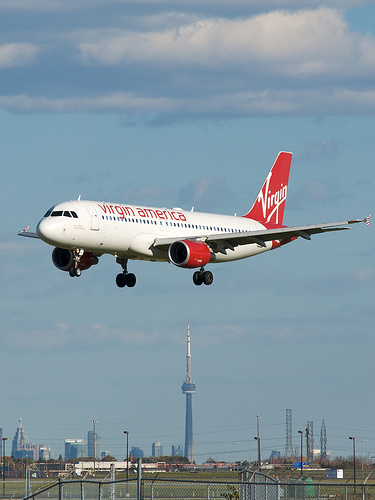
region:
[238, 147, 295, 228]
the tail of a plane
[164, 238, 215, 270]
the engine of a plane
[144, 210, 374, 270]
the wing of a plane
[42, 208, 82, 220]
the windshield of a plane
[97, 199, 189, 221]
red writing on the plane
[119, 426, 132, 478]
a black light pole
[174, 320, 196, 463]
a tower in the distance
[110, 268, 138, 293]
a wheel of the plane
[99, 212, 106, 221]
a window on the plane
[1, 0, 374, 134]
clouds in the sky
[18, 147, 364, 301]
this is a plane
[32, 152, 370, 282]
the plane is white in color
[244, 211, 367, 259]
this is the wing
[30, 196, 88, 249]
the head is streamlined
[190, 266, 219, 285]
these are the wheels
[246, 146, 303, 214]
this is the tail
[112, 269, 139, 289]
the wheels are black in color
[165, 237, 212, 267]
this is the propeller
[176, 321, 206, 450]
the tower is tall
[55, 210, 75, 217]
the screen are black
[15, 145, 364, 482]
plane close to landing near industrial town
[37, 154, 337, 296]
white plane with red writing and red highlights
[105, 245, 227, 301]
black wheels underneath the plane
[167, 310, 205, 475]
tall spire towering over other buildings and structures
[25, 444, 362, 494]
metal fencing near plane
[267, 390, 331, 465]
tall metal structures connected to wires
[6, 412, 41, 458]
old and heavy tiered building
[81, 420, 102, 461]
modern building with slanted roof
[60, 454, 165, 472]
wide and short white building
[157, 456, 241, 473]
series of red signs in front of spire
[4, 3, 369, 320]
The sky is blue.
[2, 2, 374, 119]
The clouds are white.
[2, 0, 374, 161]
The sky is partly cloudy.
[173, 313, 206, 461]
One tall building.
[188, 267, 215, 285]
The wheels are black.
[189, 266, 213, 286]
The wheels are round.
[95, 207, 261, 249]
Windows on the plane.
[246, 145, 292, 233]
Tale is red and white.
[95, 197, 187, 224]
Text says Virgin America.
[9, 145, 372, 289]
Airplane in the sky.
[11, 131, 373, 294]
airplane in the sky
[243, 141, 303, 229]
tail of an airplane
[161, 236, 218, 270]
left engine of a plane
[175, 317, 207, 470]
sky tower at an airport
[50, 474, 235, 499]
silver chain link fence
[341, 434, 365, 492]
light poles by the runway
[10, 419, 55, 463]
building in the background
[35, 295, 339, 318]
blue sky in the distance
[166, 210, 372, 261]
left wing of an airplane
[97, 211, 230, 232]
windows on an airplane